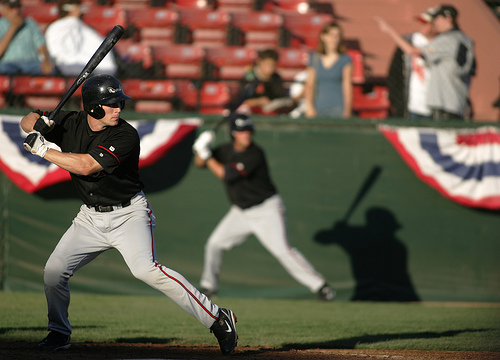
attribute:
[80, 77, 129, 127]
head — male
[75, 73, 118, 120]
helmet — one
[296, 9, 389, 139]
dress — blue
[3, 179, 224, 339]
pants — white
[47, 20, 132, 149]
bat — black, baseball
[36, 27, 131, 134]
bat — black, baseball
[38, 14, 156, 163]
bat — black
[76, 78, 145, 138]
helmet — black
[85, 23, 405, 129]
chairs — red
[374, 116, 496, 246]
bunting — red, white, blue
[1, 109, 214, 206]
bunting — blue, white, red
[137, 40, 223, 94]
seat — empty, stadium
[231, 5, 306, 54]
seat — stadium, empty